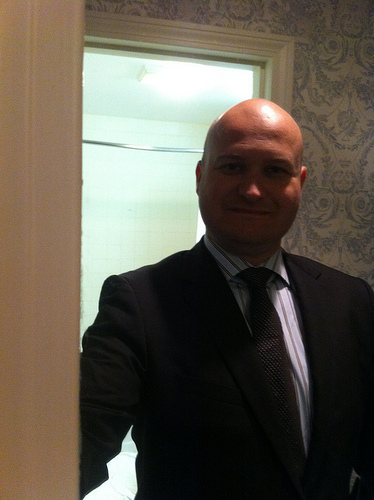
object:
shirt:
[204, 236, 318, 457]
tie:
[229, 264, 308, 474]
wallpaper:
[69, 0, 374, 286]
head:
[193, 89, 310, 254]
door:
[0, 0, 88, 500]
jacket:
[79, 243, 374, 500]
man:
[79, 92, 373, 499]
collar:
[203, 230, 291, 286]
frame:
[81, 12, 294, 61]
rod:
[77, 130, 206, 160]